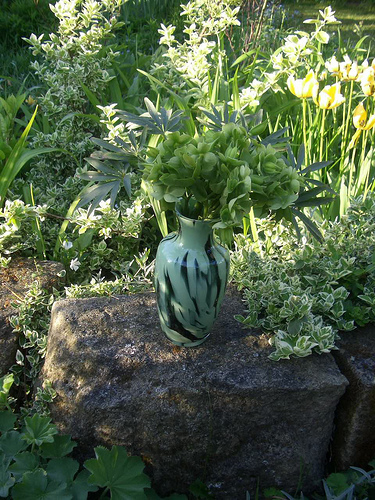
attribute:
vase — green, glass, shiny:
[142, 220, 237, 336]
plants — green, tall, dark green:
[163, 121, 289, 215]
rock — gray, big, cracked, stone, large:
[47, 317, 337, 469]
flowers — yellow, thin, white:
[273, 30, 363, 142]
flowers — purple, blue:
[279, 0, 313, 41]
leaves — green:
[54, 14, 246, 92]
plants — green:
[8, 75, 46, 202]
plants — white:
[143, 56, 216, 100]